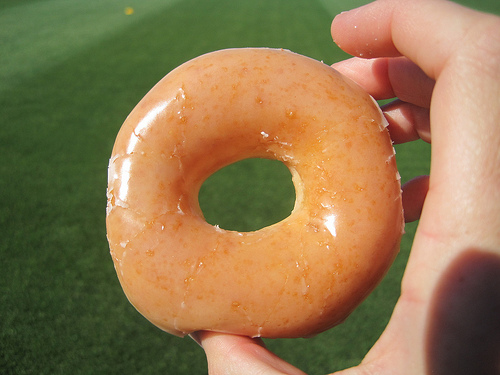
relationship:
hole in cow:
[193, 153, 298, 240] [105, 47, 407, 338]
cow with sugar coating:
[105, 47, 407, 338] [310, 186, 354, 248]